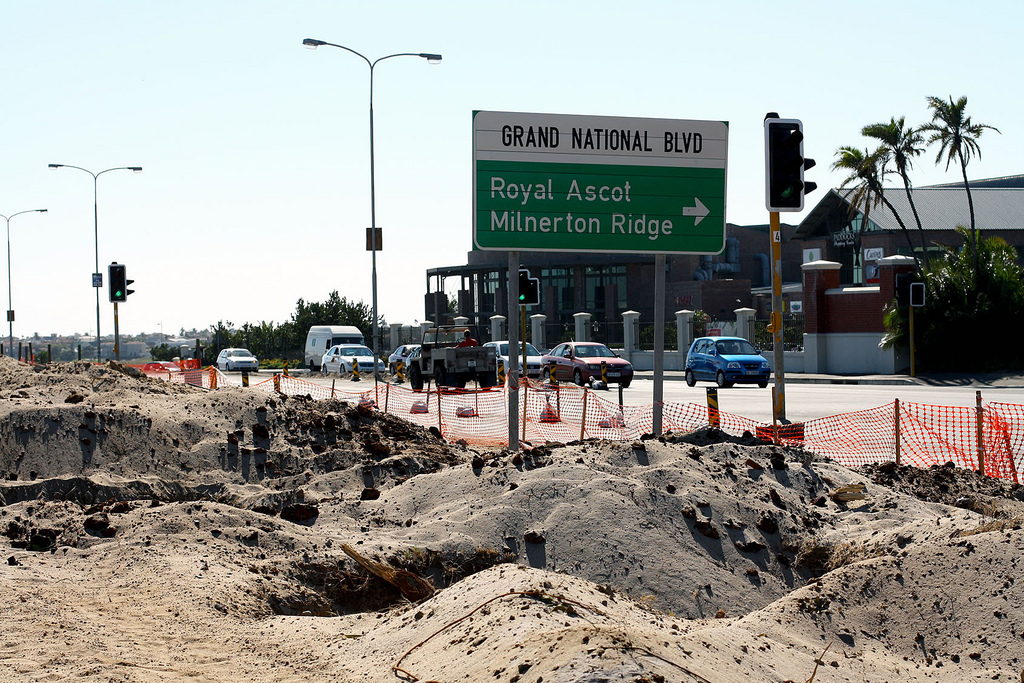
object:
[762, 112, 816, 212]
traffic light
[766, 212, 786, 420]
pole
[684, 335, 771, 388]
car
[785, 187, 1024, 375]
building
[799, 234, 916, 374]
wall